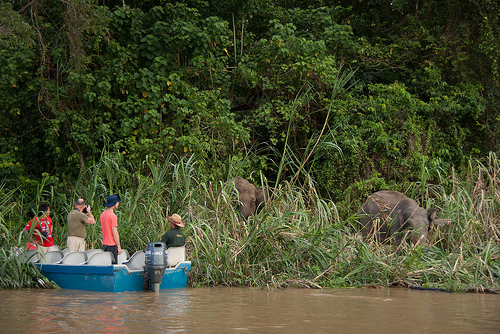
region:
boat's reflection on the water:
[43, 289, 188, 316]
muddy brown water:
[147, 289, 314, 324]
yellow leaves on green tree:
[146, 72, 201, 91]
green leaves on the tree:
[143, 54, 233, 126]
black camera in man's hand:
[70, 197, 98, 232]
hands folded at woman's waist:
[16, 195, 59, 254]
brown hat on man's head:
[165, 207, 188, 234]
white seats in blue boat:
[45, 235, 160, 273]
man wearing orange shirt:
[92, 205, 127, 250]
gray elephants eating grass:
[206, 149, 467, 269]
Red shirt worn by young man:
[97, 205, 118, 243]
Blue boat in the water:
[0, 255, 185, 295]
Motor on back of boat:
[140, 240, 165, 290]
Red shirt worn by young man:
[20, 211, 55, 246]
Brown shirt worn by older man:
[65, 207, 88, 237]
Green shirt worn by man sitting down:
[157, 225, 182, 245]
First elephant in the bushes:
[212, 170, 294, 230]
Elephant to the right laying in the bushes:
[356, 188, 431, 249]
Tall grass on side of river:
[186, 188, 491, 291]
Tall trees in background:
[3, 6, 497, 186]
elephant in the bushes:
[333, 185, 445, 249]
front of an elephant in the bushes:
[212, 172, 276, 224]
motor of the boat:
[141, 242, 167, 286]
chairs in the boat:
[31, 230, 186, 272]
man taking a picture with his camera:
[65, 195, 99, 252]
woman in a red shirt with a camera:
[16, 195, 58, 261]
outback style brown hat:
[160, 211, 185, 255]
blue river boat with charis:
[21, 230, 192, 306]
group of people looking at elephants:
[18, 185, 200, 285]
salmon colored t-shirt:
[98, 209, 117, 254]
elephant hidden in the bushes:
[344, 176, 431, 251]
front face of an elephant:
[211, 167, 291, 244]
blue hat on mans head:
[102, 191, 130, 209]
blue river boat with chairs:
[14, 233, 199, 305]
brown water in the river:
[62, 285, 424, 332]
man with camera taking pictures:
[64, 191, 96, 251]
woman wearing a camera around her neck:
[22, 201, 62, 259]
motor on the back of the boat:
[136, 244, 177, 293]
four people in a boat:
[6, 183, 221, 303]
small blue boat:
[8, 228, 209, 292]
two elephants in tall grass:
[216, 171, 495, 255]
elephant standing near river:
[356, 141, 459, 310]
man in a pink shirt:
[95, 190, 126, 252]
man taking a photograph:
[64, 191, 94, 261]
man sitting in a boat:
[122, 186, 194, 307]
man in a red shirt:
[13, 187, 51, 262]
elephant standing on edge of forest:
[314, 89, 442, 264]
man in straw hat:
[156, 186, 191, 268]